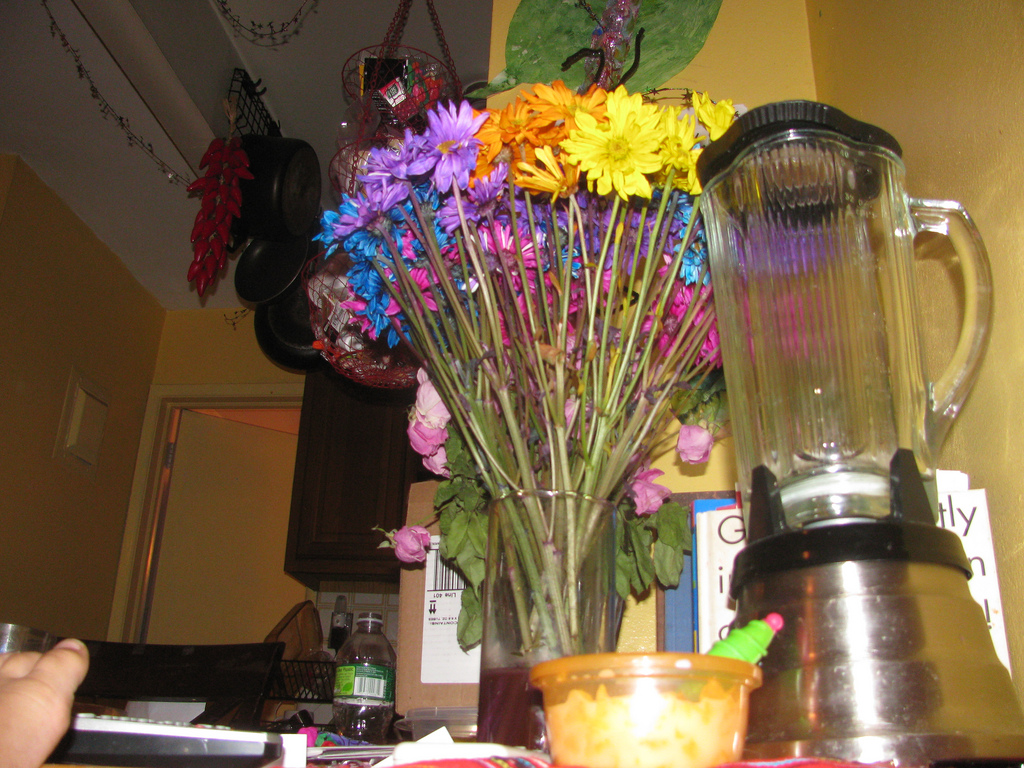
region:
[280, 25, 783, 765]
a bouquet of flowers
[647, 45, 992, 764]
blender on the side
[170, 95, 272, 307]
a string of chilis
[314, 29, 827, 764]
flowers in a vase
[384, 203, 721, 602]
stems of the flowers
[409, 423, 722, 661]
leaves on the stems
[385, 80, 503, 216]
the flower is purple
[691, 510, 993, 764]
silver base of blender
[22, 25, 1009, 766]
picture taken indoors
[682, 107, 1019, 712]
a tall blender on the table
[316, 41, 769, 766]
various flowers in a vase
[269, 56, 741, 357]
various colors of the flowers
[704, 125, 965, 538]
the blender is empty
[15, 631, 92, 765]
a person's hand on the table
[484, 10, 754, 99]
green leaf on the wall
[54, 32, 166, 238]
white painted ceiling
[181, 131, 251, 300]
Red peppers are hanging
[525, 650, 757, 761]
Orange cup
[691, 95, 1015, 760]
Blender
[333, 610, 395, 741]
Bottle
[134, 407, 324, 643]
Doors are open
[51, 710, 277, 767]
Remote control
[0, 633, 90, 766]
Foot is next to remote control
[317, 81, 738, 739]
Colorful flowers in a vase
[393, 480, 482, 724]
Brown box behind a vase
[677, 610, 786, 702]
Green plastic toy in an orange bowl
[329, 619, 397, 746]
empty plastic bottle on the counter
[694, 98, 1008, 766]
large blender on the table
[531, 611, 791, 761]
small orange bowl on the table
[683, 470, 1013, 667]
books behind the large blender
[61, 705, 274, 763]
television remote on the table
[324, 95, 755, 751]
vase full of flowers on the table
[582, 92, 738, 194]
yellow flowers in the vase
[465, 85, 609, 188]
orange flowers in the vase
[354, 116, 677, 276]
purple flowers in the vase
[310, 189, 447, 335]
blue flowers in the vase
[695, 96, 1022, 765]
An appliance on the counter.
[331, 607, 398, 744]
A bottle for holding liquid.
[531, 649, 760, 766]
A vessel for holding food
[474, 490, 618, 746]
A vessel for holding flowers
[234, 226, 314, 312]
A pan for cooking food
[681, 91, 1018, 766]
a tall gray and black blender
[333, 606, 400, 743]
an open water bottle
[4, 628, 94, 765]
the foot of a person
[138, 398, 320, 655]
an open door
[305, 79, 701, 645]
a colorful bouquet of flowers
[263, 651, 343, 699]
a black dish rack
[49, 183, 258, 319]
a white ceiling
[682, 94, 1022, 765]
a silver food blender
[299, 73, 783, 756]
a bouquet of flowers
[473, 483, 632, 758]
a glass flower vase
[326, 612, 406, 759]
a plastic beverage bottle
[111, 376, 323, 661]
an slightly opened door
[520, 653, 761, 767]
an orange plastic bowl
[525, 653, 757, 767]
the small bowl is orange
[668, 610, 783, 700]
the green and pink plastic handle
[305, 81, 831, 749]
the colorful flowers in the vase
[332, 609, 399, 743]
the plastic bottle is clear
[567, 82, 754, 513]
the flowers are yellow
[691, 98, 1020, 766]
the blender has a silver base